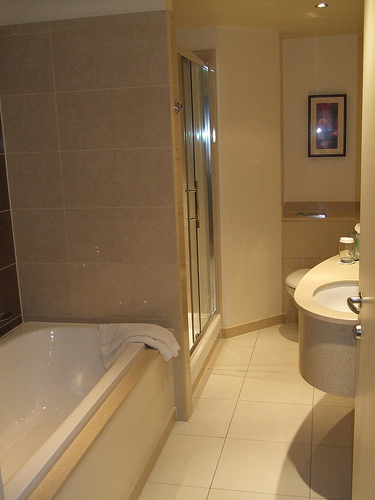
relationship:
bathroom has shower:
[0, 1, 364, 500] [177, 52, 220, 359]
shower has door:
[177, 52, 220, 359] [179, 57, 217, 353]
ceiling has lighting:
[174, 2, 364, 38] [317, 2, 328, 11]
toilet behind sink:
[285, 269, 313, 343] [312, 280, 358, 314]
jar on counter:
[339, 238, 357, 264] [295, 249, 360, 329]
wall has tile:
[0, 0, 186, 420] [0, 10, 187, 421]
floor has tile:
[139, 324, 356, 500] [139, 320, 354, 499]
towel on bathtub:
[96, 324, 180, 373] [1, 320, 176, 499]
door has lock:
[350, 2, 373, 500] [352, 325, 362, 339]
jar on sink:
[339, 238, 357, 264] [312, 280, 358, 314]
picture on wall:
[308, 94, 346, 157] [282, 33, 364, 323]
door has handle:
[179, 57, 217, 353] [188, 179, 201, 231]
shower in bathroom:
[177, 52, 220, 359] [0, 1, 364, 500]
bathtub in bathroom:
[1, 320, 176, 499] [0, 1, 364, 500]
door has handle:
[350, 2, 373, 500] [346, 294, 363, 314]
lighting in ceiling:
[317, 2, 328, 11] [174, 2, 364, 38]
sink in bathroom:
[312, 280, 358, 314] [0, 1, 364, 500]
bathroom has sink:
[0, 1, 364, 500] [312, 280, 358, 314]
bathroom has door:
[0, 1, 364, 500] [350, 2, 373, 500]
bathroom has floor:
[0, 1, 364, 500] [139, 324, 356, 500]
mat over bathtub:
[96, 324, 180, 373] [1, 320, 176, 499]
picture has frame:
[308, 94, 346, 157] [310, 95, 348, 157]